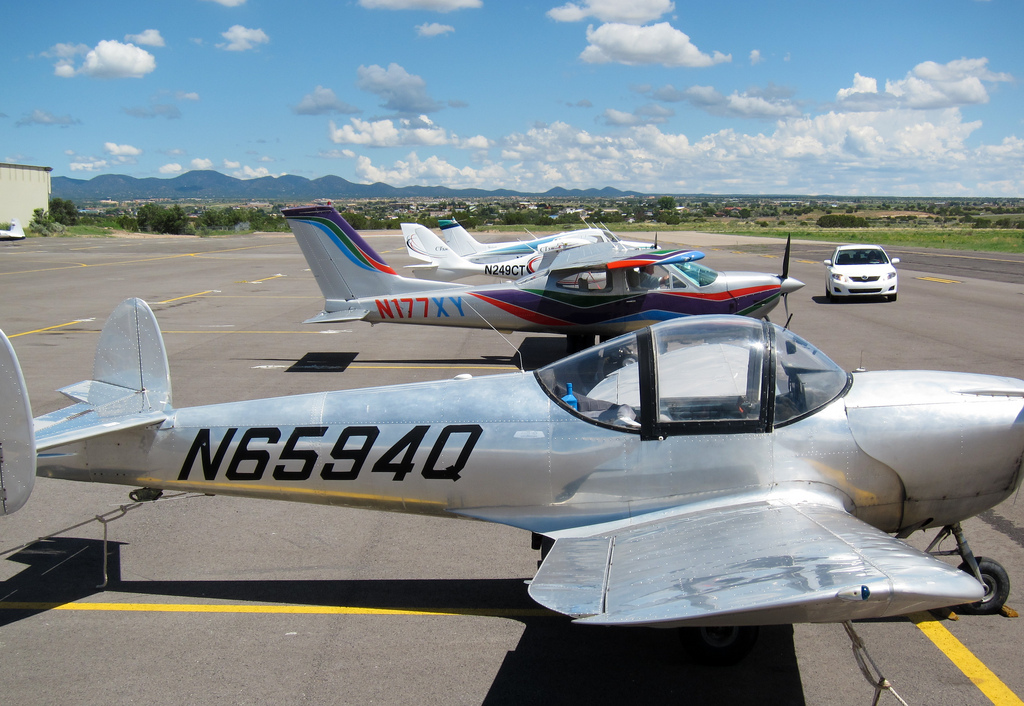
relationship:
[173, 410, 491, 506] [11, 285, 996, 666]
writing on airplane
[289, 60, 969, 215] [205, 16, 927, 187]
clouds in sky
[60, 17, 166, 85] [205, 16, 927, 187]
cloud in sky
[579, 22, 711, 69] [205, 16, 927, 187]
cloud in sky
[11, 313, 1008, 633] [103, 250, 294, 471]
airplane lined up on runway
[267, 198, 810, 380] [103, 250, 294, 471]
airplane lined up on runway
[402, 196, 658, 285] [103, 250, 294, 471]
airplane lined up on runway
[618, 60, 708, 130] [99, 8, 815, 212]
cloud in sky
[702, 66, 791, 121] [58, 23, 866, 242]
cloud in sky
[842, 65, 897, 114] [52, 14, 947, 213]
cloud in sky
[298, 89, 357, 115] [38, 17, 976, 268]
cloud in sky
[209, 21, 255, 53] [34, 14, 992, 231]
cloud in sky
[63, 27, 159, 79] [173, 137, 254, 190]
cloud in sky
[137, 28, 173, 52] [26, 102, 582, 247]
cloud in sky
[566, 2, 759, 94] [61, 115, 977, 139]
cloud in sky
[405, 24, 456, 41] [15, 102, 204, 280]
cloud in sky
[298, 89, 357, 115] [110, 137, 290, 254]
cloud in sky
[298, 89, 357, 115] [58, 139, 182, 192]
cloud in sky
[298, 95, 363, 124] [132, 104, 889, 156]
cloud in sky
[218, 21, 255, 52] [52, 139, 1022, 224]
cloud in sky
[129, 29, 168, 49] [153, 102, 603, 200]
cloud in sky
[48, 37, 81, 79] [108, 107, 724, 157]
cloud in sky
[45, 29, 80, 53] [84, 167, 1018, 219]
cloud in sky